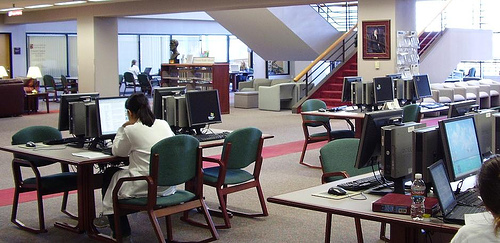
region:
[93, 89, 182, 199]
Person working on a computer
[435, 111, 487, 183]
Computer screen is turned on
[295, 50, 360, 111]
A set of red stairs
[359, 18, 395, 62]
A framed photo on the wall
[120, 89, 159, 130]
Black hair in a ponytail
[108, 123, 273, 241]
Two chairs are green and brown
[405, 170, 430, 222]
A bottle of water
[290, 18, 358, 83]
A brown wooden stair railing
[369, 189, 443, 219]
A closed red book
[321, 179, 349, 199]
A black computer mouse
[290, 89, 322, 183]
Green and wooden chair at a desk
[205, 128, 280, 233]
Green and wooden chair at a desk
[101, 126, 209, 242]
Green and wooden chair at a desk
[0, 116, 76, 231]
Green and wooden chair at a desk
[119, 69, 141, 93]
Green and wooden chair at a desk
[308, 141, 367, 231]
Green and wooden chair at a desk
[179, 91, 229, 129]
Small black computer monitor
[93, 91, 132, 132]
Small black computer monitor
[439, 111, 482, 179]
Small black computer monitor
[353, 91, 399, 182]
Small black computer monitor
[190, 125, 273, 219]
a green and brown chair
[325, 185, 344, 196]
a black computer mouse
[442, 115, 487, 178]
a large computer monitor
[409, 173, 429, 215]
a tall water bottle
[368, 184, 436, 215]
part of a red notebook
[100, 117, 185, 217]
a large white lab coat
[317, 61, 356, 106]
part of a red stairway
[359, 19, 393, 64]
a large picture frame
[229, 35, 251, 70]
a window of a building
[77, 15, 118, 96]
a large white pole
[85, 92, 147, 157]
computer on a desk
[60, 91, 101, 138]
computer on a desk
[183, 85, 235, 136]
computer on a desk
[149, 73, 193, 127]
computer on a desk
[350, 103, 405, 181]
computer on a desk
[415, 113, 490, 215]
computer on a desk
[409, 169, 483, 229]
computer on a desk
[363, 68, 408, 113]
computer on a desk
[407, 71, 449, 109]
computer on a desk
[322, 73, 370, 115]
computer on a desk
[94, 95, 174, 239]
a woman in a white coat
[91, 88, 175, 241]
woman sitting at a computer desk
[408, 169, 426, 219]
a water bottle on the desk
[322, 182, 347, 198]
a black computer mouse on the desk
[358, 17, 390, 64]
a wood framed picture on the wall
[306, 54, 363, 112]
red staircase in the computer lab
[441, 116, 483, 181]
a turned on computer screen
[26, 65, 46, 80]
a bright lamp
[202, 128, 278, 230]
a wood and green chair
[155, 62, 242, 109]
a bookshelf full of books